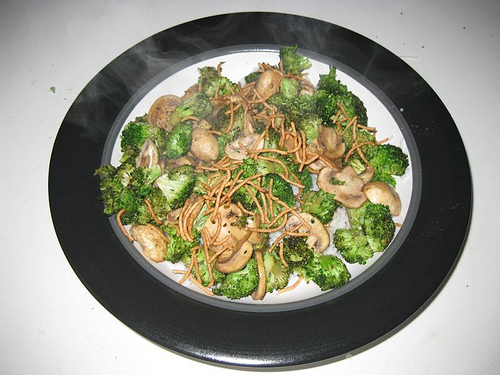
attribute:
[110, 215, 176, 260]
mushroom — cooked, cut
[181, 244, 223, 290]
noodles — brown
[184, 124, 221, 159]
mushroom — cut, cooked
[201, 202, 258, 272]
mushroom — cut, cooked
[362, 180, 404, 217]
mushroom — cut, cooked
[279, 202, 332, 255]
mushroom — cooked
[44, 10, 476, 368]
plate — white, black, black and white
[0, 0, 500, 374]
table — white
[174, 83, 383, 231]
vegetables — hot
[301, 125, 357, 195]
mushrooms — brown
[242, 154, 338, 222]
broccoli — dark green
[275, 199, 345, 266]
mushrooms — brown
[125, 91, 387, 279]
plate — white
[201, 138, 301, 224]
noodles — crunchy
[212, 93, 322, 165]
noodles — thin